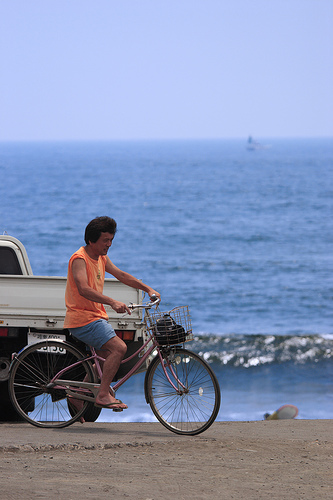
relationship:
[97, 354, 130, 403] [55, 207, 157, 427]
leg of man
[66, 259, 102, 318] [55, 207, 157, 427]
tank top of man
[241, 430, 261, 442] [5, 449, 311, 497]
sand on beach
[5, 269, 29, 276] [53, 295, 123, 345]
window of truck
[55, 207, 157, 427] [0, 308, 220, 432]
man riding bike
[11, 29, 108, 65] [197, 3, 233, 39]
clouds in sky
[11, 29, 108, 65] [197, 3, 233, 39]
clouds on sky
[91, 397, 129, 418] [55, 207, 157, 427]
sandals on man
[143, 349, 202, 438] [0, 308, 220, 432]
wheel on bike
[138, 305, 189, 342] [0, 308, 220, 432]
basket on bike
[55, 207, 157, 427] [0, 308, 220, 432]
man on bike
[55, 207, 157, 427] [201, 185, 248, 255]
man near water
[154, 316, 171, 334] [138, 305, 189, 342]
bag in basket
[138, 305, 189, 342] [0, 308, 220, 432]
basket in bike